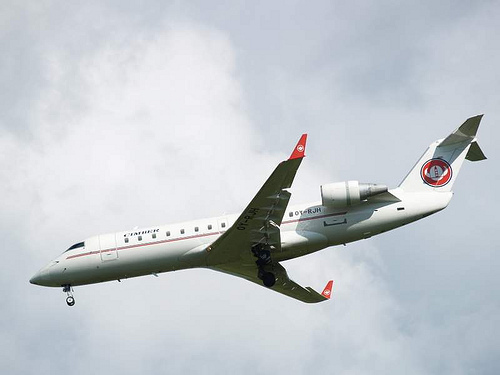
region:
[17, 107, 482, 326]
the plane is white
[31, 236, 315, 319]
plane wheels are out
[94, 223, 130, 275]
plane door is closed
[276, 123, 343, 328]
end of plane's wings are red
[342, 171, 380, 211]
end of engine is gray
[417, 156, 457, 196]
red circle on tail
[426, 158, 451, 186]
white logo on circle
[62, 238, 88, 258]
front windows are black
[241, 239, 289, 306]
plane's wheels are black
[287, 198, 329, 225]
black lettering on plane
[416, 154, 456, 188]
red and white viking helmet logo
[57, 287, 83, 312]
small black and white landing wheels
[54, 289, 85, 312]
airplane landing gear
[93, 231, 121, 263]
white metal door on side of airplane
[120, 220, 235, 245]
row of airplane windows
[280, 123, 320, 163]
red bits of metal at the end of the wings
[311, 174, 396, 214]
engine of the airplane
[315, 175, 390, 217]
powering device necessary to keep plane in air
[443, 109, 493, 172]
tail fins on airplane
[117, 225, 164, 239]
logo on airplane indicating airline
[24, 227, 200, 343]
nose of the aircraft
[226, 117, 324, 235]
wing of the plane with a red tip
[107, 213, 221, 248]
windows in the plane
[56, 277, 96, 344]
wheel for landing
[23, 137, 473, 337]
A plane about to land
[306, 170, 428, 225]
engine of the plane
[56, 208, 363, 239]
red stripe going down the middle of the plane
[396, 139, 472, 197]
red symbol on the tail of the plane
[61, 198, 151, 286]
door for the plane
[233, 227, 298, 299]
folded up wheels for the plane to land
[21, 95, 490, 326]
This is a plane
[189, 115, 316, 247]
this is the right wing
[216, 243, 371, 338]
this is the left wing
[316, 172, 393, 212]
this is an engine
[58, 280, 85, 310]
this is the front landing gear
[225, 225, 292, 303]
this is landing gear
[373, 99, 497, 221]
this is a tail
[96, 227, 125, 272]
this is a door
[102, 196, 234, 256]
these are the windows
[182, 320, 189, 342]
this is the color white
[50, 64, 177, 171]
the sky is cloudy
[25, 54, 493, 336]
this is a small passenger jet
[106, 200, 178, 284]
black text for logo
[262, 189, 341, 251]
the callsign of the plane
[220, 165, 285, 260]
the plane is oy-rjh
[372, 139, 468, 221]
a red and white logo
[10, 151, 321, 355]
the wheels are down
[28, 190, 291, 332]
the plane has three wheels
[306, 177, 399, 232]
the jet engine of the plane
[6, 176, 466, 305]
the plane has a red stripe